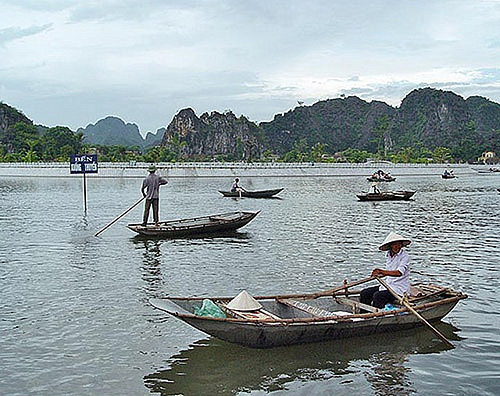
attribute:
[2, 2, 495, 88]
sky — clear, cloudy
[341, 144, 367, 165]
tree — green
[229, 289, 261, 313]
hat — white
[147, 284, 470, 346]
boat — canoe style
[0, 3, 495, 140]
sky — cloudy, clear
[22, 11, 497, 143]
sky — cloudy, clear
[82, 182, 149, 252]
pole — long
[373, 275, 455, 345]
oar — long, brown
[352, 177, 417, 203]
boat — small, white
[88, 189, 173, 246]
oar — long, brown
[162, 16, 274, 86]
cloudy sky — clear